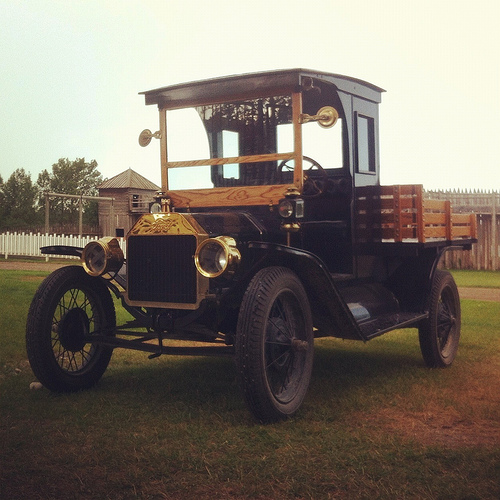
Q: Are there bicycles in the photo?
A: No, there are no bicycles.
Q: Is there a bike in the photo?
A: No, there are no bikes.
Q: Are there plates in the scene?
A: Yes, there is a plate.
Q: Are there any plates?
A: Yes, there is a plate.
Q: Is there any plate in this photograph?
A: Yes, there is a plate.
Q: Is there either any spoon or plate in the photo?
A: Yes, there is a plate.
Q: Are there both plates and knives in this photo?
A: No, there is a plate but no knives.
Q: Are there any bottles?
A: No, there are no bottles.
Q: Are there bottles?
A: No, there are no bottles.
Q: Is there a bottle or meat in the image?
A: No, there are no bottles or meat.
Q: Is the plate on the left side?
A: Yes, the plate is on the left of the image.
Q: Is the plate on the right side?
A: No, the plate is on the left of the image.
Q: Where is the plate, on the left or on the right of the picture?
A: The plate is on the left of the image.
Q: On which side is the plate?
A: The plate is on the left of the image.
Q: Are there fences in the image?
A: Yes, there is a fence.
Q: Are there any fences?
A: Yes, there is a fence.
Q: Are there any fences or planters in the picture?
A: Yes, there is a fence.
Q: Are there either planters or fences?
A: Yes, there is a fence.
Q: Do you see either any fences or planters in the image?
A: Yes, there is a fence.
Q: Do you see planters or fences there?
A: Yes, there is a fence.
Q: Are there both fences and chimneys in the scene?
A: No, there is a fence but no chimneys.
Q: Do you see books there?
A: No, there are no books.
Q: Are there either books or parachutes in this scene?
A: No, there are no books or parachutes.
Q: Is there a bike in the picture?
A: No, there are no bikes.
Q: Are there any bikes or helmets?
A: No, there are no bikes or helmets.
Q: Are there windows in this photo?
A: Yes, there is a window.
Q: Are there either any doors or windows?
A: Yes, there is a window.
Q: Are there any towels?
A: No, there are no towels.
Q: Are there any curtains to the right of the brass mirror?
A: Yes, there is a curtain to the right of the mirror.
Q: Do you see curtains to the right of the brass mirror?
A: Yes, there is a curtain to the right of the mirror.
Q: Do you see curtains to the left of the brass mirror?
A: No, the curtain is to the right of the mirror.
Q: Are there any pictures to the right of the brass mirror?
A: No, there is a curtain to the right of the mirror.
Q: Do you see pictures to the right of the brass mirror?
A: No, there is a curtain to the right of the mirror.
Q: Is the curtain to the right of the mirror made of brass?
A: Yes, the curtain is to the right of the mirror.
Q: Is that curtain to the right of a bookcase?
A: No, the curtain is to the right of the mirror.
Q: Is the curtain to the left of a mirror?
A: No, the curtain is to the right of a mirror.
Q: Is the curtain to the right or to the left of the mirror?
A: The curtain is to the right of the mirror.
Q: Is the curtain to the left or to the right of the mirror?
A: The curtain is to the right of the mirror.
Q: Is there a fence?
A: Yes, there is a fence.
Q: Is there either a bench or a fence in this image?
A: Yes, there is a fence.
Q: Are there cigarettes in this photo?
A: No, there are no cigarettes.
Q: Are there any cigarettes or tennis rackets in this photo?
A: No, there are no cigarettes or tennis rackets.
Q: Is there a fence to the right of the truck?
A: Yes, there is a fence to the right of the truck.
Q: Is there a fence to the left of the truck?
A: No, the fence is to the right of the truck.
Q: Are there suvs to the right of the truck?
A: No, there is a fence to the right of the truck.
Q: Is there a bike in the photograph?
A: No, there are no bikes.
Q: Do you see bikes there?
A: No, there are no bikes.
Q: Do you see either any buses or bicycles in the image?
A: No, there are no bicycles or buses.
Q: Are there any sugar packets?
A: No, there are no sugar packets.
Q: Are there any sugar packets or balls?
A: No, there are no sugar packets or balls.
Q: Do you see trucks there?
A: Yes, there is a truck.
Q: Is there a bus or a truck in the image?
A: Yes, there is a truck.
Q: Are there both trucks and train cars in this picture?
A: No, there is a truck but no train cars.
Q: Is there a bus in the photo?
A: No, there are no buses.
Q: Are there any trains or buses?
A: No, there are no buses or trains.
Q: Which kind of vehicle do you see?
A: The vehicle is a truck.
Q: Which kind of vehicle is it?
A: The vehicle is a truck.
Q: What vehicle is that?
A: That is a truck.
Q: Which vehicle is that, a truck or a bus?
A: That is a truck.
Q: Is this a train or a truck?
A: This is a truck.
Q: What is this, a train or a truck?
A: This is a truck.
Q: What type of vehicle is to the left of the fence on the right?
A: The vehicle is a truck.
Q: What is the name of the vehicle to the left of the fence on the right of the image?
A: The vehicle is a truck.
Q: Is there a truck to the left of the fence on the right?
A: Yes, there is a truck to the left of the fence.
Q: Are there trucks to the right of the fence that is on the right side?
A: No, the truck is to the left of the fence.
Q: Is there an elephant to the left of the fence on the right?
A: No, there is a truck to the left of the fence.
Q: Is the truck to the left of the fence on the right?
A: Yes, the truck is to the left of the fence.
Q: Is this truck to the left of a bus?
A: No, the truck is to the left of the fence.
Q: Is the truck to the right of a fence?
A: No, the truck is to the left of a fence.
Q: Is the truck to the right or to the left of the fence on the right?
A: The truck is to the left of the fence.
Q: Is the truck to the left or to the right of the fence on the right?
A: The truck is to the left of the fence.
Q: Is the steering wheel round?
A: Yes, the steering wheel is round.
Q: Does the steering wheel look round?
A: Yes, the steering wheel is round.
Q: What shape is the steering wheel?
A: The steering wheel is round.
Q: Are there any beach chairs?
A: No, there are no beach chairs.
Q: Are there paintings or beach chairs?
A: No, there are no beach chairs or paintings.